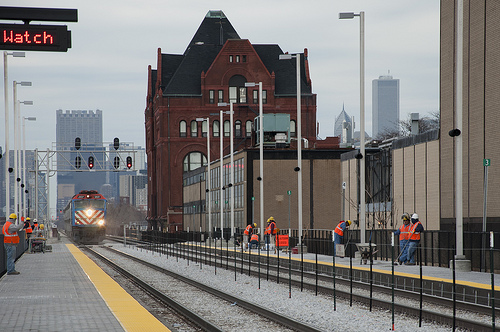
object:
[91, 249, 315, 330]
track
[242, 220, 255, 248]
railway workers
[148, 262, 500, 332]
rails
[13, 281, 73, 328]
pavement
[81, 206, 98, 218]
light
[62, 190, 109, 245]
train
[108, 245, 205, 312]
tracks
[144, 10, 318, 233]
building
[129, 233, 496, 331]
poles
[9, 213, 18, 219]
helmet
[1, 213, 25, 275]
man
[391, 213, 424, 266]
workers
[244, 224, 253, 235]
vests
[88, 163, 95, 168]
red signal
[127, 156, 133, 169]
signal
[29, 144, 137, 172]
support structure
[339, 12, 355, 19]
fixtures